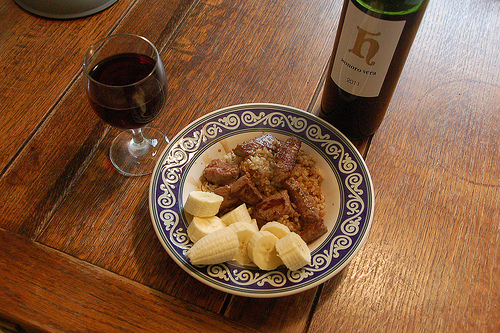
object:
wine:
[320, 0, 430, 138]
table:
[0, 0, 500, 332]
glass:
[81, 30, 176, 178]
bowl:
[149, 103, 377, 300]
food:
[185, 132, 327, 271]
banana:
[273, 233, 313, 271]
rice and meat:
[237, 144, 265, 166]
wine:
[89, 50, 167, 127]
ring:
[415, 73, 499, 193]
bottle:
[322, 0, 431, 129]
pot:
[11, 0, 125, 21]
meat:
[276, 138, 299, 158]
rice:
[253, 159, 259, 164]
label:
[330, 0, 406, 98]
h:
[348, 24, 382, 66]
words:
[363, 70, 377, 76]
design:
[157, 108, 364, 291]